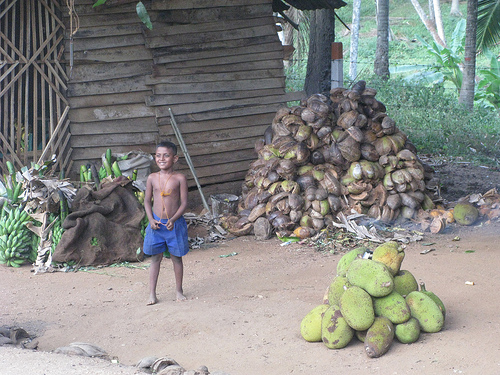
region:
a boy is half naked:
[136, 152, 236, 331]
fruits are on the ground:
[297, 223, 459, 343]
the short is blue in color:
[134, 224, 201, 256]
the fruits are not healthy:
[346, 244, 458, 365]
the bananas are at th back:
[13, 148, 125, 235]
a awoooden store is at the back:
[141, 37, 240, 139]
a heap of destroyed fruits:
[266, 109, 410, 233]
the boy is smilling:
[98, 139, 223, 276]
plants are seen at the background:
[401, 57, 492, 151]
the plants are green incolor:
[396, 76, 498, 153]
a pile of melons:
[291, 236, 453, 358]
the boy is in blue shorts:
[130, 127, 201, 309]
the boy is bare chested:
[139, 118, 202, 309]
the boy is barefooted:
[140, 133, 206, 318]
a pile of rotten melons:
[247, 76, 444, 233]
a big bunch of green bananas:
[1, 187, 56, 276]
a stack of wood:
[96, 18, 249, 141]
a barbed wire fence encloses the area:
[356, 44, 467, 115]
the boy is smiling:
[148, 125, 197, 292]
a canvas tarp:
[66, 188, 138, 260]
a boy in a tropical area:
[6, 28, 314, 333]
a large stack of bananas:
[1, 172, 39, 267]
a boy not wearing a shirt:
[133, 136, 195, 310]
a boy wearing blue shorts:
[121, 143, 202, 261]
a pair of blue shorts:
[140, 214, 192, 268]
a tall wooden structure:
[6, 0, 285, 144]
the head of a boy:
[146, 137, 183, 175]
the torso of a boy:
[127, 170, 202, 222]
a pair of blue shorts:
[139, 213, 191, 262]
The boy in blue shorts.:
[125, 130, 205, 311]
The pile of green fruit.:
[302, 238, 474, 351]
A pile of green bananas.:
[3, 192, 35, 272]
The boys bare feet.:
[141, 288, 199, 312]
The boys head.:
[152, 145, 180, 170]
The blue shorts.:
[144, 216, 185, 259]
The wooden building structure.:
[1, 3, 299, 243]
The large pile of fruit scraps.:
[247, 86, 457, 234]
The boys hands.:
[150, 213, 180, 232]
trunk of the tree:
[462, 2, 476, 113]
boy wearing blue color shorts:
[143, 219, 184, 256]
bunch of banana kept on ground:
[0, 187, 30, 269]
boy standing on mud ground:
[138, 289, 193, 311]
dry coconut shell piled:
[289, 109, 344, 194]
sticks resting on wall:
[168, 109, 182, 138]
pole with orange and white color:
[330, 44, 344, 91]